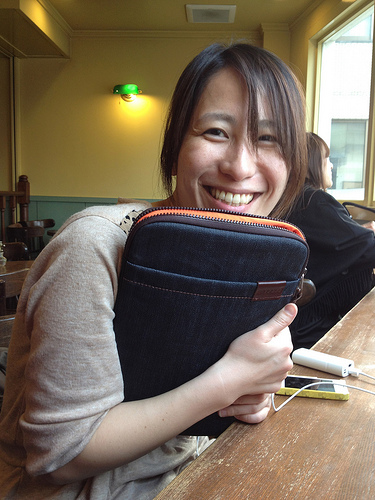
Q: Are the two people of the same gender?
A: Yes, all the people are female.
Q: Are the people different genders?
A: No, all the people are female.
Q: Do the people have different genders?
A: No, all the people are female.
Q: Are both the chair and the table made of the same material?
A: Yes, both the chair and the table are made of wood.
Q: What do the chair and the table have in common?
A: The material, both the chair and the table are wooden.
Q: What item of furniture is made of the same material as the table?
A: The chair is made of the same material as the table.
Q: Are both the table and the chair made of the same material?
A: Yes, both the table and the chair are made of wood.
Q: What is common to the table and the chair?
A: The material, both the table and the chair are wooden.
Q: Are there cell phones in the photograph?
A: Yes, there is a cell phone.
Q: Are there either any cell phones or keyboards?
A: Yes, there is a cell phone.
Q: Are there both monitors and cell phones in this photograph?
A: No, there is a cell phone but no monitors.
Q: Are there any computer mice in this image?
A: No, there are no computer mice.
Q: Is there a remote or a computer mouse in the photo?
A: No, there are no computer mice or remote controls.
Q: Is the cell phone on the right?
A: Yes, the cell phone is on the right of the image.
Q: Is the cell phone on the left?
A: No, the cell phone is on the right of the image.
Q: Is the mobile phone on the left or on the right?
A: The mobile phone is on the right of the image.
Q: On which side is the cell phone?
A: The cell phone is on the right of the image.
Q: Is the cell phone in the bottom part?
A: Yes, the cell phone is in the bottom of the image.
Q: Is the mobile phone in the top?
A: No, the mobile phone is in the bottom of the image.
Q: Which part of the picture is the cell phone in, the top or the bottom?
A: The cell phone is in the bottom of the image.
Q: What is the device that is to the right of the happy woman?
A: The device is a cell phone.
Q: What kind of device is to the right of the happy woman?
A: The device is a cell phone.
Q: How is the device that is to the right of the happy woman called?
A: The device is a cell phone.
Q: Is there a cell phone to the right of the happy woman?
A: Yes, there is a cell phone to the right of the woman.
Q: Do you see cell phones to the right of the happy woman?
A: Yes, there is a cell phone to the right of the woman.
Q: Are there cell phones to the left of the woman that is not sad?
A: No, the cell phone is to the right of the woman.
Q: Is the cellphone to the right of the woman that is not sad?
A: Yes, the cellphone is to the right of the woman.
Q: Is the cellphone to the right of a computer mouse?
A: No, the cellphone is to the right of the woman.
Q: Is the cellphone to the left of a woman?
A: No, the cellphone is to the right of a woman.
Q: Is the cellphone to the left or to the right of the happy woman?
A: The cellphone is to the right of the woman.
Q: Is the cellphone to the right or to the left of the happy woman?
A: The cellphone is to the right of the woman.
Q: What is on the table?
A: The cellphone is on the table.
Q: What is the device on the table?
A: The device is a cell phone.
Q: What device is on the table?
A: The device is a cell phone.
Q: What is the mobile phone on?
A: The mobile phone is on the table.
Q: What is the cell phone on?
A: The mobile phone is on the table.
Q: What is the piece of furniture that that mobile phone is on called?
A: The piece of furniture is a table.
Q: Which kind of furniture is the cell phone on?
A: The mobile phone is on the table.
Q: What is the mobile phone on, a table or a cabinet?
A: The mobile phone is on a table.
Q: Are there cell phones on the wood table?
A: Yes, there is a cell phone on the table.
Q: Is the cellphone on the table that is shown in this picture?
A: Yes, the cellphone is on the table.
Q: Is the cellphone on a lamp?
A: No, the cellphone is on the table.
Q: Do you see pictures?
A: No, there are no pictures.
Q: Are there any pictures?
A: No, there are no pictures.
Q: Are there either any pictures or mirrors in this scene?
A: No, there are no pictures or mirrors.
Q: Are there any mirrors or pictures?
A: No, there are no pictures or mirrors.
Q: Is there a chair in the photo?
A: Yes, there is a chair.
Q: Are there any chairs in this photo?
A: Yes, there is a chair.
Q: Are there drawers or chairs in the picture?
A: Yes, there is a chair.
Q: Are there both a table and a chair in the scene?
A: Yes, there are both a chair and a table.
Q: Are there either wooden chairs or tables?
A: Yes, there is a wood chair.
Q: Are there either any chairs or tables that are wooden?
A: Yes, the chair is wooden.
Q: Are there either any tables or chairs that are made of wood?
A: Yes, the chair is made of wood.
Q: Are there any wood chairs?
A: Yes, there is a wood chair.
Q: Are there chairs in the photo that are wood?
A: Yes, there is a wood chair.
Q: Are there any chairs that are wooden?
A: Yes, there is a chair that is wooden.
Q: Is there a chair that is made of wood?
A: Yes, there is a chair that is made of wood.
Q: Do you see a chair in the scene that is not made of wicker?
A: Yes, there is a chair that is made of wood.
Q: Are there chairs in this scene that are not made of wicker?
A: Yes, there is a chair that is made of wood.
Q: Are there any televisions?
A: No, there are no televisions.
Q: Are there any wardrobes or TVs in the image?
A: No, there are no TVs or wardrobes.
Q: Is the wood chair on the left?
A: Yes, the chair is on the left of the image.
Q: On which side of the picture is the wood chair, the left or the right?
A: The chair is on the left of the image.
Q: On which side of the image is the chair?
A: The chair is on the left of the image.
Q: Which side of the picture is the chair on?
A: The chair is on the left of the image.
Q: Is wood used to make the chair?
A: Yes, the chair is made of wood.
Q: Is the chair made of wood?
A: Yes, the chair is made of wood.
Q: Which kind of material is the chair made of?
A: The chair is made of wood.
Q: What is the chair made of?
A: The chair is made of wood.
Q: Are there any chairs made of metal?
A: No, there is a chair but it is made of wood.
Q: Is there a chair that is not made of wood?
A: No, there is a chair but it is made of wood.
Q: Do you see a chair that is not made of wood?
A: No, there is a chair but it is made of wood.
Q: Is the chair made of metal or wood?
A: The chair is made of wood.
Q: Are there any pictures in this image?
A: No, there are no pictures.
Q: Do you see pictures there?
A: No, there are no pictures.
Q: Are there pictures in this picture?
A: No, there are no pictures.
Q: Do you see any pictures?
A: No, there are no pictures.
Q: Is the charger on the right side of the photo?
A: Yes, the charger is on the right of the image.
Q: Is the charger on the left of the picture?
A: No, the charger is on the right of the image.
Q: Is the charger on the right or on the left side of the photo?
A: The charger is on the right of the image.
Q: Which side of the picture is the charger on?
A: The charger is on the right of the image.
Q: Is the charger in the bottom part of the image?
A: Yes, the charger is in the bottom of the image.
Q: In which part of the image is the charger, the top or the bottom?
A: The charger is in the bottom of the image.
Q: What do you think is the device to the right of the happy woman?
A: The device is a charger.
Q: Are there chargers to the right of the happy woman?
A: Yes, there is a charger to the right of the woman.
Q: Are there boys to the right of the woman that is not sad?
A: No, there is a charger to the right of the woman.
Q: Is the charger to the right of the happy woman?
A: Yes, the charger is to the right of the woman.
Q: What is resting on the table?
A: The charger is resting on the table.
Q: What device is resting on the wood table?
A: The device is a charger.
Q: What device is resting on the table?
A: The device is a charger.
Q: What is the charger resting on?
A: The charger is resting on the table.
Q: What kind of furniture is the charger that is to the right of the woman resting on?
A: The charger is resting on the table.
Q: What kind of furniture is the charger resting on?
A: The charger is resting on the table.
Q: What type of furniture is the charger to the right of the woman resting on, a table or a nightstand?
A: The charger is resting on a table.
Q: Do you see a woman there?
A: Yes, there is a woman.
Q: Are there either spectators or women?
A: Yes, there is a woman.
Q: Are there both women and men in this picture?
A: No, there is a woman but no men.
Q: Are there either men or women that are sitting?
A: Yes, the woman is sitting.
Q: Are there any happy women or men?
A: Yes, there is a happy woman.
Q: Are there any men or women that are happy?
A: Yes, the woman is happy.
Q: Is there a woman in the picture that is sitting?
A: Yes, there is a woman that is sitting.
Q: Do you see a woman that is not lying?
A: Yes, there is a woman that is sitting .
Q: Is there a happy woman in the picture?
A: Yes, there is a happy woman.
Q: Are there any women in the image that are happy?
A: Yes, there is a woman that is happy.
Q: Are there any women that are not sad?
A: Yes, there is a happy woman.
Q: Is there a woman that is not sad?
A: Yes, there is a happy woman.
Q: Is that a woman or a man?
A: That is a woman.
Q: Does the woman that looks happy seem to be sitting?
A: Yes, the woman is sitting.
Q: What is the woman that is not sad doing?
A: The woman is sitting.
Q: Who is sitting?
A: The woman is sitting.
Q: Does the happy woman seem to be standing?
A: No, the woman is sitting.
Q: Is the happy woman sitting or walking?
A: The woman is sitting.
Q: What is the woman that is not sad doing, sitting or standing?
A: The woman is sitting.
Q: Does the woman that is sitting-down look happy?
A: Yes, the woman is happy.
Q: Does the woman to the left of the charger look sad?
A: No, the woman is happy.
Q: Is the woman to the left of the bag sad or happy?
A: The woman is happy.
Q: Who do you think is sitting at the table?
A: The woman is sitting at the table.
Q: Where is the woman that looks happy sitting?
A: The woman is sitting at the table.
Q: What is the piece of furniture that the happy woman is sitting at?
A: The piece of furniture is a table.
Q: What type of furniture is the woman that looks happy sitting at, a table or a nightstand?
A: The woman is sitting at a table.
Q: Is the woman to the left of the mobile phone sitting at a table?
A: Yes, the woman is sitting at a table.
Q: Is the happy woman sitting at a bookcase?
A: No, the woman is sitting at a table.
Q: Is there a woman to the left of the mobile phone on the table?
A: Yes, there is a woman to the left of the cellphone.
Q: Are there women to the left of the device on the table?
A: Yes, there is a woman to the left of the cellphone.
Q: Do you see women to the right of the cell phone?
A: No, the woman is to the left of the cell phone.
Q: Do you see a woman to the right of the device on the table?
A: No, the woman is to the left of the cell phone.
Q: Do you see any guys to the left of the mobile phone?
A: No, there is a woman to the left of the mobile phone.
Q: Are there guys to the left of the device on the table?
A: No, there is a woman to the left of the mobile phone.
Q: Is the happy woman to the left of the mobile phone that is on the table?
A: Yes, the woman is to the left of the mobile phone.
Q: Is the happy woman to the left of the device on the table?
A: Yes, the woman is to the left of the mobile phone.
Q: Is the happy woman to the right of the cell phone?
A: No, the woman is to the left of the cell phone.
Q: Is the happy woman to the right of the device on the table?
A: No, the woman is to the left of the cell phone.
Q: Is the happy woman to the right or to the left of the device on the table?
A: The woman is to the left of the cellphone.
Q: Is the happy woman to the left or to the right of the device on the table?
A: The woman is to the left of the cellphone.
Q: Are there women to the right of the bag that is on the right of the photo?
A: No, the woman is to the left of the bag.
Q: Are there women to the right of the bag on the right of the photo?
A: No, the woman is to the left of the bag.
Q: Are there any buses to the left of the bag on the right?
A: No, there is a woman to the left of the bag.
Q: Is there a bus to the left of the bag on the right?
A: No, there is a woman to the left of the bag.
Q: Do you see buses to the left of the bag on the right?
A: No, there is a woman to the left of the bag.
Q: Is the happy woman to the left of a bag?
A: Yes, the woman is to the left of a bag.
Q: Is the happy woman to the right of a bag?
A: No, the woman is to the left of a bag.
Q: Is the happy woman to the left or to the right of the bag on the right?
A: The woman is to the left of the bag.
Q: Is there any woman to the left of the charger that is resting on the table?
A: Yes, there is a woman to the left of the charger.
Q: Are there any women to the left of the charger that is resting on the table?
A: Yes, there is a woman to the left of the charger.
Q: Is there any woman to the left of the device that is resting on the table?
A: Yes, there is a woman to the left of the charger.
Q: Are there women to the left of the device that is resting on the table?
A: Yes, there is a woman to the left of the charger.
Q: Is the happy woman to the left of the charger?
A: Yes, the woman is to the left of the charger.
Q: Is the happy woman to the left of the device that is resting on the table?
A: Yes, the woman is to the left of the charger.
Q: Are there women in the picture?
A: Yes, there is a woman.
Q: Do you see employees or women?
A: Yes, there is a woman.